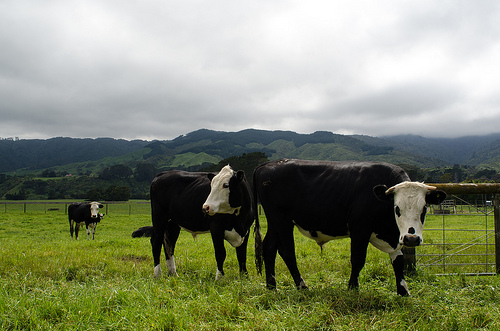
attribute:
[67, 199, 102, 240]
cow — standing, black, white, alert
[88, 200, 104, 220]
head — white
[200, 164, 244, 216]
head — white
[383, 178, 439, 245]
head — white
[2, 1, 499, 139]
sky — cloudy, overcast, cloud covered, gray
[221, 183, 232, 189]
eye — black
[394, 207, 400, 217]
eye — black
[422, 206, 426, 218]
eye — black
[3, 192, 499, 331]
pasture — grassy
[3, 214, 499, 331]
grass — green, long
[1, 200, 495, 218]
fence — wired, in good condition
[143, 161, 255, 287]
cow — black, white, looking right, looking away, spotted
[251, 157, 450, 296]
cow — black, white, alert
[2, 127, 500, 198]
mountainside — hilly, forest covered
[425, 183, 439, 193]
horn — white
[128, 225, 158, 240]
cow — lying down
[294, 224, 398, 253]
underbelly — white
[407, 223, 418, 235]
spot — black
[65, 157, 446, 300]
cows — in the pasture, grouped, in the field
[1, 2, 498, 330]
scene — daytime, outdoors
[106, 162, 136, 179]
trees — green